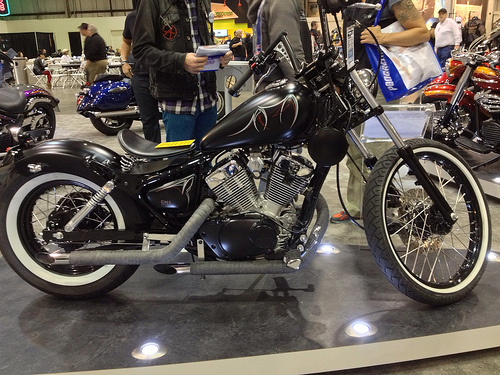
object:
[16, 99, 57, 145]
tire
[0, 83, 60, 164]
bike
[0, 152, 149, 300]
wheel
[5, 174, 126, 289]
stripe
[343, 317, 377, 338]
light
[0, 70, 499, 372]
floor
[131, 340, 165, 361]
light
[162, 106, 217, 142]
jeans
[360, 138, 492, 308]
whitewall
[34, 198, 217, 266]
exhaust pipes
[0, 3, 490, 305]
bike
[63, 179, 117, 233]
shock absorbers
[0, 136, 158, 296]
back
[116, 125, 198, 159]
seat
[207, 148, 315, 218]
motor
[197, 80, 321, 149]
gas tank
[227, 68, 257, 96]
handle bars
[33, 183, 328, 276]
display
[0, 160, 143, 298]
tire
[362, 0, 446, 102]
bag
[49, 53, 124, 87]
tables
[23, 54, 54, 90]
chairs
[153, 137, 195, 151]
tag